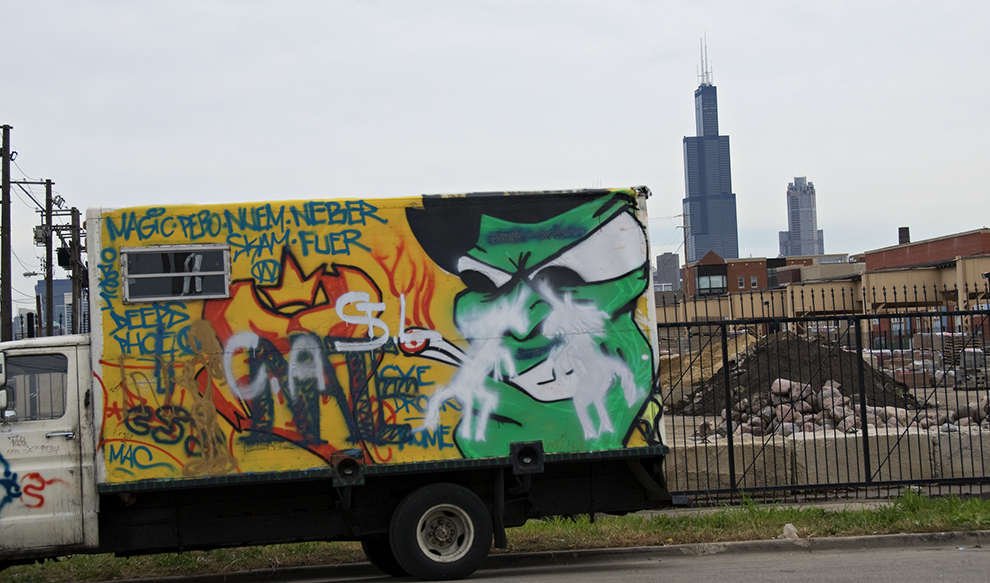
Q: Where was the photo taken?
A: Near a graffitti van.